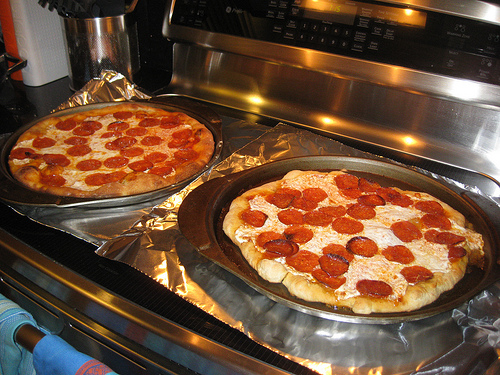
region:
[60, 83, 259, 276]
a part of omlet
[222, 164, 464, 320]
a big omlet in plate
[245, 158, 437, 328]
a big omlet in stove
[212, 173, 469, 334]
a big omlet in plate on stove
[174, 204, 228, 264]
a round plate in stove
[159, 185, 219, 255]
a part of the plate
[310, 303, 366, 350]
light on the plate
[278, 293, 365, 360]
light on the stove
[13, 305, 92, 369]
a bottle near stove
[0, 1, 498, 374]
Two pizzas on top of a stainless steel oven.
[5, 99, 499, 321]
Two pizzas on top of pizza pans.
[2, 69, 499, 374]
The pizza pans are on top of tin foil.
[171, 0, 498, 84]
Touch buttons on a black panel.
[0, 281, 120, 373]
Dish towels hanging on the oven door handle.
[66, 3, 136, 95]
Metal container for cooking utensils.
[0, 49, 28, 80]
Handle of a pan that is next to the stove.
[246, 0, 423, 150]
Lights reflecting off of the top of the stove.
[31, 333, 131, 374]
blue dish towel with a pink designed stripe.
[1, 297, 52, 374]
Light blue dish towel with a white stripe.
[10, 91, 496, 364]
THE PIZZAS ARE ON THE FOIL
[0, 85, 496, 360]
THE PIZZAS ARE SIDE BY SIDE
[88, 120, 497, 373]
THE FOIL HAS WRINKLES IN IT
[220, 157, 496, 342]
THE PEPPERONI IS ON THE PIZZA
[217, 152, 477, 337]
THE CHEESE IS ON THE PIZZA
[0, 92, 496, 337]
THE PIZZA IS IN PANS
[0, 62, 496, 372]
THE FOIL IS UNDER THE PIZZA PANS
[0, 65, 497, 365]
TWO PIZZAS SIDE BY SIDE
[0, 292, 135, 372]
THE HANDLE OF THE OVEN HAS TOWELS ON IT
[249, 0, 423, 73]
THE OVEN HAS MANY BUTTONS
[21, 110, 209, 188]
round pizza on stove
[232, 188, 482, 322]
round pizza on stove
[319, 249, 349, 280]
red pepperoni piece on pizza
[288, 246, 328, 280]
red pepperoni piece on pizza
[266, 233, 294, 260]
red pepperoni piece on pizza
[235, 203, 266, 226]
red pepperoni piece on pizza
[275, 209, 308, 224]
red pepperoni piece on pizza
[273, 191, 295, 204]
red pepperoni piece on pizza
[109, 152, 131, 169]
red pepperoni piece on pizza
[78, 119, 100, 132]
red pepperoni piece on pizza